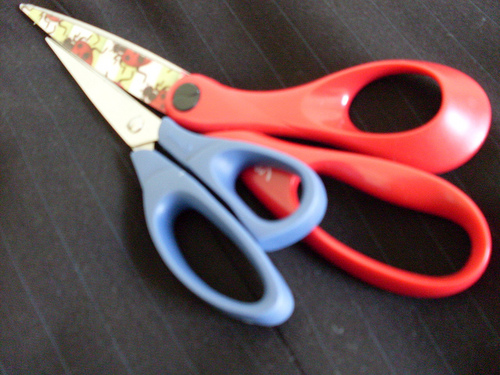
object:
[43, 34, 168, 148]
blades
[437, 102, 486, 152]
light reflection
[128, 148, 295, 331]
blue handles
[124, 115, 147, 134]
bolt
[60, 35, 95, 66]
bug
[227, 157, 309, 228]
hole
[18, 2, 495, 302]
red scissor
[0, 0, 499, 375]
cloth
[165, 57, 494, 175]
handle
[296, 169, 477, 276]
hole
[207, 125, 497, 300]
scissor handle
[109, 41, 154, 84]
design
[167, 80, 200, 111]
bolt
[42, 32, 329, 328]
scissors